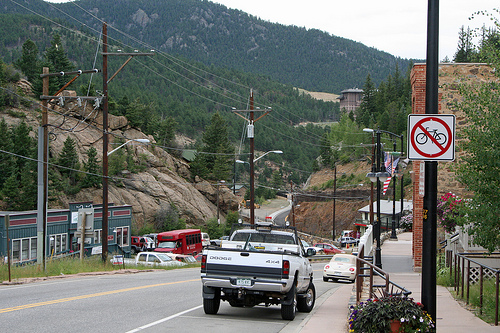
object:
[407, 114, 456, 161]
sign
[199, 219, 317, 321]
truck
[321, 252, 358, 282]
car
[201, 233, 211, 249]
van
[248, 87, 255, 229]
pole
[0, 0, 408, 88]
mountain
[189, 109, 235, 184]
tree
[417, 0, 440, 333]
pole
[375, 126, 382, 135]
light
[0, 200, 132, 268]
building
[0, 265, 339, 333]
road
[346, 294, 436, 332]
flowers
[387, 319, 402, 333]
pot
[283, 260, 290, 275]
tail light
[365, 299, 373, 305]
flower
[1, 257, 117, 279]
grass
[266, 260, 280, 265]
number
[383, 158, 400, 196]
flag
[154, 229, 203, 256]
bus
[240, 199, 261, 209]
tractor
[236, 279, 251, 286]
plate